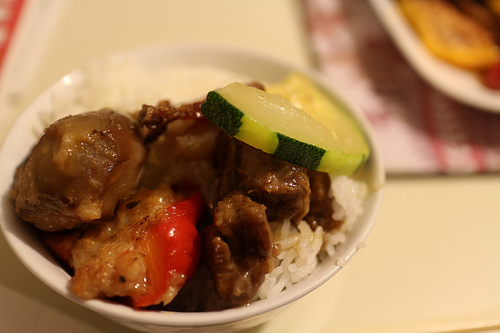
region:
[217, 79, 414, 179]
cucumber on the plate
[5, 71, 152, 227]
chicken in the bowl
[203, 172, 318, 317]
beef inside the bowl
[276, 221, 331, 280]
rice in the white bowl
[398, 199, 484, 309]
a tan table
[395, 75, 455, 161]
a white and red mat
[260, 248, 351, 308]
a white bowl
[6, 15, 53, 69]
white around the table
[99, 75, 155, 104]
white rice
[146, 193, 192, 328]
Red accent on the piece of chicken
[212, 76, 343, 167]
Slice of zucchini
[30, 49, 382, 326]
White bowl with food inside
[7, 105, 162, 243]
Piece of brown meat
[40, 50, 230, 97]
White rice in background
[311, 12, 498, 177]
Red and white placemat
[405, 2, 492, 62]
Orange piece of food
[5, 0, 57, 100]
Red and white placemat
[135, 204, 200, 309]
Red piece of pepper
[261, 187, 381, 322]
Clump of white rice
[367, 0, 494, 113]
Edge of a white dish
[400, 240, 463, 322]
a table with a white tablecloth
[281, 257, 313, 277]
grains of white rice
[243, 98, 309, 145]
a slice of green cucumber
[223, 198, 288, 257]
thin slices of brown beef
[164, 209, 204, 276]
the red skin of a tomato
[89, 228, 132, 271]
the white flesh of a shrimp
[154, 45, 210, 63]
the edge of a white bowl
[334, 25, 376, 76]
a red and white placemate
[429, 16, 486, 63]
a slice of yellow squash on a plate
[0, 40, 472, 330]
a tasty meal on the table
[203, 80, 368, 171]
slice of green squash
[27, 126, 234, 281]
cooked brown meat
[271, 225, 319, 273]
white grains of rice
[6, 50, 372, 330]
plate of food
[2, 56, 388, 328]
white plate of food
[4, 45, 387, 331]
plate of food containing rice, squash, and meat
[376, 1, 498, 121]
plate containing food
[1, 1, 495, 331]
two plates of food on the table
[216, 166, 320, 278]
white rice under the brown meat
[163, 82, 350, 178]
green slice of squash on top of meat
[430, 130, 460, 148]
part of a cloth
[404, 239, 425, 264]
section of a dinner table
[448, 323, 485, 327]
edge of a brown table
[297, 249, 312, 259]
portion of cooked rice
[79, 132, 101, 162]
meat on a small bowl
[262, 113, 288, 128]
piece of cucumber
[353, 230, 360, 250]
edge of a small bowl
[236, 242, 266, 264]
piece of cooked meat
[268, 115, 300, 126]
green vegetable on a plate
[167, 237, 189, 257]
red part on meat